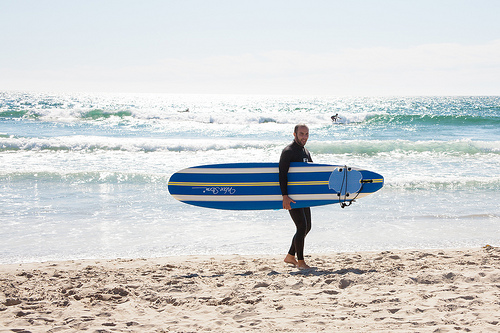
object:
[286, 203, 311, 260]
legs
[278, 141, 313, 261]
wet suit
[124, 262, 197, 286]
foot marks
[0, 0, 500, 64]
sky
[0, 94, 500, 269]
water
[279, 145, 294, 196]
arm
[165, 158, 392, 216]
silver phone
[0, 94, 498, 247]
ocean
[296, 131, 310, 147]
facial hair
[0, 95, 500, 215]
waves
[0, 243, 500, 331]
sand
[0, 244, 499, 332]
beach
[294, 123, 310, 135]
dark hair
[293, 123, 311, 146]
head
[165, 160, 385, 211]
surf board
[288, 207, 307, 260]
leg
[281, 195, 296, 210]
hand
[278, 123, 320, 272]
guy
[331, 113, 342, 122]
person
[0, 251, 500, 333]
track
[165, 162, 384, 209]
board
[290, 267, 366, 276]
shadow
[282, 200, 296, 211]
fingers